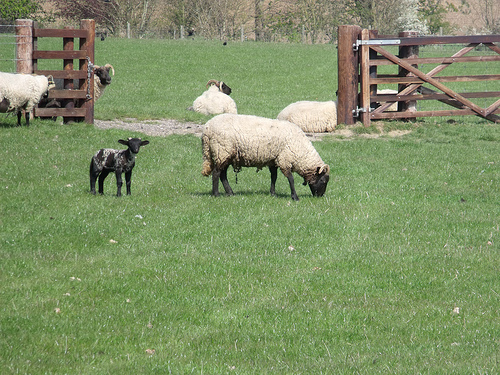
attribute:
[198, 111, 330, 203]
sheep — white, grazing, adult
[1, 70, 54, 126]
sheep — white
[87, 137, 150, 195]
sheep — black, baby, white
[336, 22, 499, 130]
fence — wooden, brown, open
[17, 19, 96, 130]
fence — wooden, brown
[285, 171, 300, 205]
leg — black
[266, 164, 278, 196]
leg — black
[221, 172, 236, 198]
leg — black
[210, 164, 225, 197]
leg — black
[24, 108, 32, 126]
leg — black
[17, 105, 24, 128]
leg — black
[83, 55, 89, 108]
chain — metal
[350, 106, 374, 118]
hinge — metal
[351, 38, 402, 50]
hinge — metal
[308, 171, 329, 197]
face — black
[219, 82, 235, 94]
face — black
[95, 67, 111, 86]
face — black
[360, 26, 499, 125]
gate — open, wooden, brown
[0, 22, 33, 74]
fence — wire